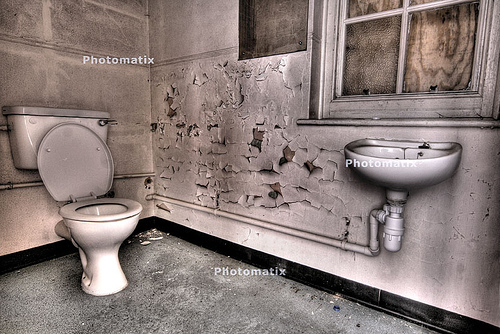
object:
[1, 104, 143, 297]
toilet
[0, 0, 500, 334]
bathroom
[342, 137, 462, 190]
basin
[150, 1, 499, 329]
wall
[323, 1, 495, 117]
window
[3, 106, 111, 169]
tank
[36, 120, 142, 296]
toilet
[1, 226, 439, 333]
floor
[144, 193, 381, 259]
pipe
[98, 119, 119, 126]
flush control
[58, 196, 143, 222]
toilet seat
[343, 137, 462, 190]
sink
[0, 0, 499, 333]
room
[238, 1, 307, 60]
mirror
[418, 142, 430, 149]
tap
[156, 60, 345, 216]
paint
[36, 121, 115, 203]
lid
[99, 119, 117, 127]
handle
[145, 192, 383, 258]
plumbing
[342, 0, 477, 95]
plywood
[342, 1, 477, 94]
boards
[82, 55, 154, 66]
watermark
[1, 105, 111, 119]
cover